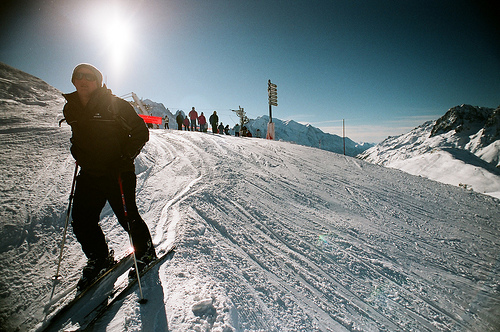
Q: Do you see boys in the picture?
A: No, there are no boys.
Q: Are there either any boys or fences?
A: No, there are no boys or fences.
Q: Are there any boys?
A: No, there are no boys.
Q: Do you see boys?
A: No, there are no boys.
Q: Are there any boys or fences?
A: No, there are no boys or fences.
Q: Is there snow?
A: Yes, there is snow.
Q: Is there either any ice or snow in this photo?
A: Yes, there is snow.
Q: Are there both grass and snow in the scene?
A: No, there is snow but no grass.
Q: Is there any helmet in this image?
A: No, there are no helmets.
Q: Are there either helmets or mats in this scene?
A: No, there are no helmets or mats.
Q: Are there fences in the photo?
A: No, there are no fences.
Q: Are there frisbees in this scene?
A: No, there are no frisbees.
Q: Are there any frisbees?
A: No, there are no frisbees.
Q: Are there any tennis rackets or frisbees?
A: No, there are no frisbees or tennis rackets.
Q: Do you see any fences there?
A: No, there are no fences.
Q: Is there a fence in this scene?
A: No, there are no fences.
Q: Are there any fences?
A: No, there are no fences.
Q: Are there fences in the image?
A: No, there are no fences.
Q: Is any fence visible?
A: No, there are no fences.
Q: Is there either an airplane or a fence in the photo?
A: No, there are no fences or airplanes.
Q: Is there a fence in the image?
A: No, there are no fences.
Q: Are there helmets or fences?
A: No, there are no fences or helmets.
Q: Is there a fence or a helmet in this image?
A: No, there are no fences or helmets.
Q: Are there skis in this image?
A: Yes, there are skis.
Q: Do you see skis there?
A: Yes, there are skis.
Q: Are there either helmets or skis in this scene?
A: Yes, there are skis.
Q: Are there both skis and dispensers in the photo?
A: No, there are skis but no dispensers.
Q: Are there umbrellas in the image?
A: No, there are no umbrellas.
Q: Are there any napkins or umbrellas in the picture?
A: No, there are no umbrellas or napkins.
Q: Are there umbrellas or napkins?
A: No, there are no umbrellas or napkins.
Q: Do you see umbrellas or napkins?
A: No, there are no umbrellas or napkins.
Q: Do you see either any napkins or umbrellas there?
A: No, there are no umbrellas or napkins.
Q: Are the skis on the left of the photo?
A: Yes, the skis are on the left of the image.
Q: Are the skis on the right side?
A: No, the skis are on the left of the image.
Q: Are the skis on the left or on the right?
A: The skis are on the left of the image.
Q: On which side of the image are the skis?
A: The skis are on the left of the image.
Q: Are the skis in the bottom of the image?
A: Yes, the skis are in the bottom of the image.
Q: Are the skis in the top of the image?
A: No, the skis are in the bottom of the image.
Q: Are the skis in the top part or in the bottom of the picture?
A: The skis are in the bottom of the image.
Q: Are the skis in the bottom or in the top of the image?
A: The skis are in the bottom of the image.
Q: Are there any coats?
A: Yes, there is a coat.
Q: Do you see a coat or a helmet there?
A: Yes, there is a coat.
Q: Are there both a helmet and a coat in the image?
A: No, there is a coat but no helmets.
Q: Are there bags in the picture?
A: No, there are no bags.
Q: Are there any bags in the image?
A: No, there are no bags.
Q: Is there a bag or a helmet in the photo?
A: No, there are no bags or helmets.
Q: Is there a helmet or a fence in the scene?
A: No, there are no fences or helmets.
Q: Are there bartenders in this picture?
A: No, there are no bartenders.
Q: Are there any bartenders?
A: No, there are no bartenders.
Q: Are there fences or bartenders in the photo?
A: No, there are no bartenders or fences.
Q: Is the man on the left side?
A: Yes, the man is on the left of the image.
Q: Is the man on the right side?
A: No, the man is on the left of the image.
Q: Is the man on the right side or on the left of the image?
A: The man is on the left of the image.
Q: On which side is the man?
A: The man is on the left of the image.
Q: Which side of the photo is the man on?
A: The man is on the left of the image.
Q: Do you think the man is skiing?
A: Yes, the man is skiing.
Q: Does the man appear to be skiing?
A: Yes, the man is skiing.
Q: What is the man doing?
A: The man is skiing.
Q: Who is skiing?
A: The man is skiing.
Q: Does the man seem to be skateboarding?
A: No, the man is skiing.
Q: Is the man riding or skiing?
A: The man is skiing.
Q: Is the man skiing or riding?
A: The man is skiing.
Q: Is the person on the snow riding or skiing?
A: The man is skiing.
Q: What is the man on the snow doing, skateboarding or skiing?
A: The man is skiing.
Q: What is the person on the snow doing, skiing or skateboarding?
A: The man is skiing.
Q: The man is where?
A: The man is on the snow.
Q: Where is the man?
A: The man is on the snow.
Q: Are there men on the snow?
A: Yes, there is a man on the snow.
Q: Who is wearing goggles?
A: The man is wearing goggles.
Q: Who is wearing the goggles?
A: The man is wearing goggles.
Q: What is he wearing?
A: The man is wearing goggles.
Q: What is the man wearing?
A: The man is wearing goggles.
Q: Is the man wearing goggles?
A: Yes, the man is wearing goggles.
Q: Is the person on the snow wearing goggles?
A: Yes, the man is wearing goggles.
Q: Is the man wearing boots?
A: No, the man is wearing goggles.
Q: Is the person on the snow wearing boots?
A: No, the man is wearing goggles.